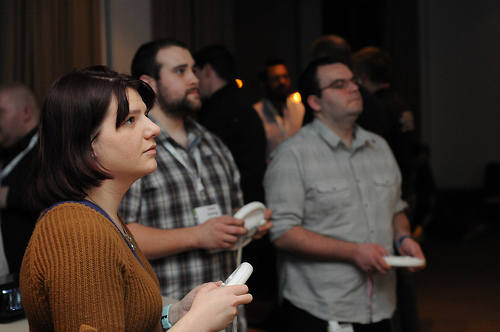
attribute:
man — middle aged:
[262, 56, 426, 330]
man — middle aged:
[249, 50, 435, 328]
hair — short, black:
[300, 55, 347, 102]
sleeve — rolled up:
[250, 154, 322, 298]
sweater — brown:
[46, 193, 173, 330]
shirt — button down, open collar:
[263, 115, 408, 322]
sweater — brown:
[18, 202, 162, 327]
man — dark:
[249, 45, 474, 327]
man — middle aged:
[133, 49, 213, 136]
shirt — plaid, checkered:
[118, 107, 258, 329]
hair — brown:
[21, 63, 158, 204]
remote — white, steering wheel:
[216, 199, 267, 257]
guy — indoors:
[260, 52, 428, 326]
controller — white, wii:
[375, 252, 427, 269]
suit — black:
[207, 92, 284, 288]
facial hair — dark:
[154, 76, 206, 116]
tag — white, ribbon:
[160, 140, 237, 222]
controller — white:
[225, 261, 262, 298]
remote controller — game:
[221, 260, 253, 282]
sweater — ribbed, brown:
[34, 201, 152, 329]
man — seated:
[0, 84, 55, 279]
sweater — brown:
[5, 188, 166, 330]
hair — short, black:
[110, 32, 190, 102]